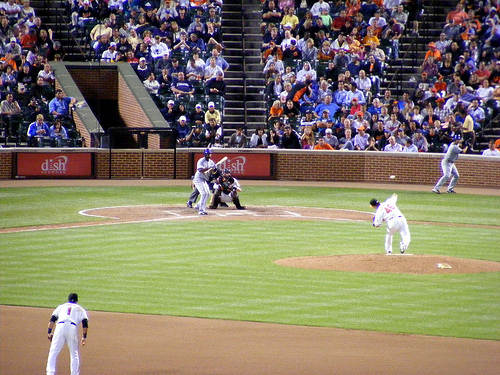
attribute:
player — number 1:
[44, 278, 117, 374]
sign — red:
[13, 145, 97, 177]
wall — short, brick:
[6, 138, 499, 182]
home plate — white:
[202, 202, 262, 221]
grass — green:
[150, 240, 267, 315]